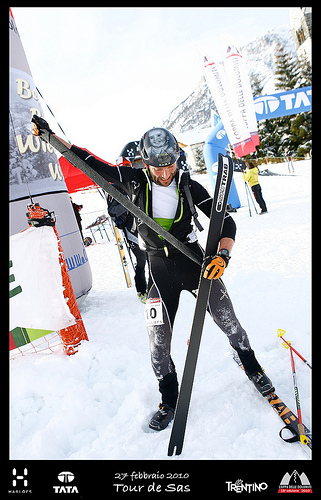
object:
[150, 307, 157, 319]
number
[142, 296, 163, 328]
sticker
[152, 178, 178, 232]
shirt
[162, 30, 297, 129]
peak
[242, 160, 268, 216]
person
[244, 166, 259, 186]
shirt